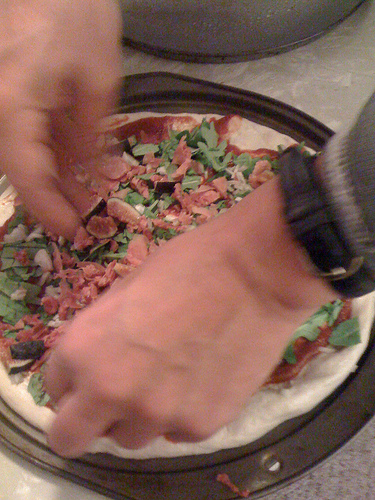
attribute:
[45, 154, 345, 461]
hand — blurry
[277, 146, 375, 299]
watch — black, leather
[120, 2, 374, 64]
plate — round, black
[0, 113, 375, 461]
pizza — uncooked, homemade, raw, sauced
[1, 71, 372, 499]
pan — metal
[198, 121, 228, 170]
leaf — green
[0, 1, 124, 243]
hand — blurry